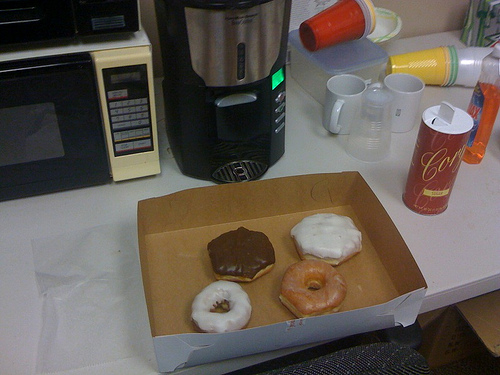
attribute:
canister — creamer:
[409, 107, 465, 219]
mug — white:
[323, 78, 367, 132]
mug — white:
[378, 77, 421, 136]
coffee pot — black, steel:
[159, 3, 300, 173]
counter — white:
[2, 31, 497, 371]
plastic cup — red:
[303, 10, 372, 42]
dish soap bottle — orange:
[466, 44, 499, 165]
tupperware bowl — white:
[291, 34, 383, 99]